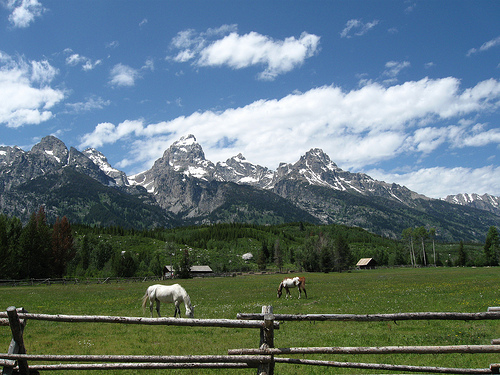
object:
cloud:
[0, 53, 58, 127]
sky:
[4, 0, 497, 202]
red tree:
[52, 213, 79, 278]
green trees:
[0, 209, 42, 279]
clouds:
[279, 87, 402, 164]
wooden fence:
[3, 304, 498, 371]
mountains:
[0, 133, 498, 278]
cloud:
[341, 17, 380, 38]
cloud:
[61, 47, 93, 69]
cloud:
[465, 36, 498, 59]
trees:
[486, 233, 498, 270]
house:
[356, 257, 376, 271]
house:
[165, 265, 214, 278]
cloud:
[174, 24, 323, 81]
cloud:
[0, 0, 45, 27]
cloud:
[364, 165, 499, 197]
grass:
[3, 271, 493, 358]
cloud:
[106, 62, 136, 88]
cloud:
[78, 75, 498, 171]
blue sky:
[1, 0, 499, 193]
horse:
[275, 277, 309, 299]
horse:
[141, 284, 196, 317]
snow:
[187, 166, 204, 177]